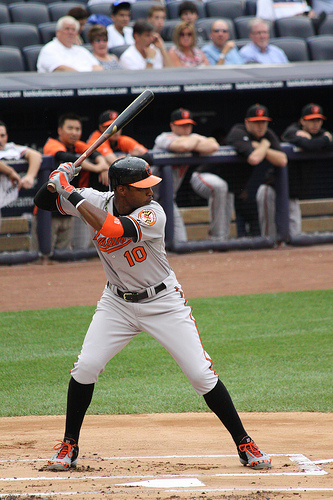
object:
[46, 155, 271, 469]
man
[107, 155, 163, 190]
helmet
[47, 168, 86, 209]
glove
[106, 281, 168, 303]
belt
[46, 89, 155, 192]
bat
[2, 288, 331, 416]
grass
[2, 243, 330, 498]
ground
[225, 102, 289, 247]
players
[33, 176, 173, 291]
shirt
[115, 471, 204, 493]
plate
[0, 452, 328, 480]
box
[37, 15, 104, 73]
people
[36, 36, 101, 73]
shirt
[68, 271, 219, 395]
pants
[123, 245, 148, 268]
ten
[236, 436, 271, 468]
shoes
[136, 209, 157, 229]
logo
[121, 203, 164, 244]
sleeve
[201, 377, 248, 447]
sock